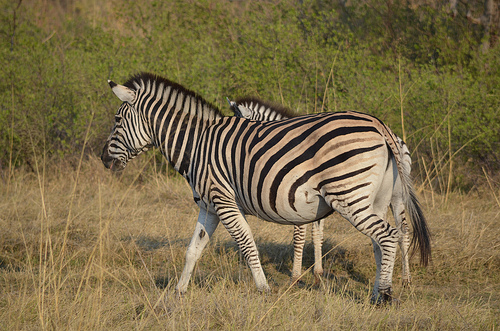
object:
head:
[100, 70, 158, 172]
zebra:
[81, 60, 434, 304]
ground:
[306, 207, 326, 248]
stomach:
[238, 187, 335, 226]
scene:
[0, 0, 499, 331]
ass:
[321, 111, 408, 216]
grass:
[0, 53, 500, 330]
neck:
[147, 77, 200, 179]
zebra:
[98, 71, 431, 308]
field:
[0, 0, 499, 331]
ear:
[107, 77, 137, 104]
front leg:
[178, 207, 220, 289]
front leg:
[215, 206, 269, 289]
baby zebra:
[226, 91, 415, 282]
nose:
[100, 148, 109, 165]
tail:
[382, 118, 434, 269]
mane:
[119, 68, 227, 130]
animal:
[100, 71, 434, 309]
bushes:
[0, 0, 498, 174]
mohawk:
[103, 64, 251, 123]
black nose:
[101, 144, 107, 168]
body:
[95, 63, 435, 311]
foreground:
[0, 206, 499, 330]